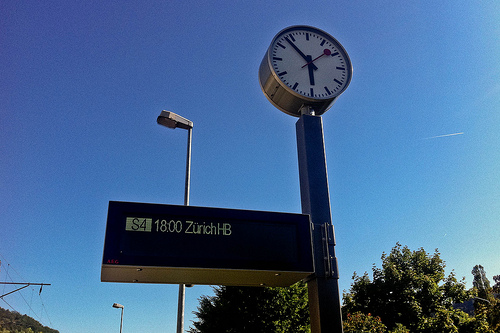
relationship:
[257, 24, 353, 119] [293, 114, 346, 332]
clock sitting on top of pole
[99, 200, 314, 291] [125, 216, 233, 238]
sign says s4 18:00 zurich hb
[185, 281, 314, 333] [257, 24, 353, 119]
tree are standing behind clock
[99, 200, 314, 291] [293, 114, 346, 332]
sign attached to pole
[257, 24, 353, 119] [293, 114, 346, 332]
clock on a pole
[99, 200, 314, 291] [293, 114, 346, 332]
sign attached to a pole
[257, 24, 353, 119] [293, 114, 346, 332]
clock standing on a pole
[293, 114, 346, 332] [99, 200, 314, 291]
pole holding up a sign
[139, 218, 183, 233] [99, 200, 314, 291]
numbers are on sign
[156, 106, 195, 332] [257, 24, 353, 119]
street light close to clock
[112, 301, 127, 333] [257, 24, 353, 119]
street light far from clock